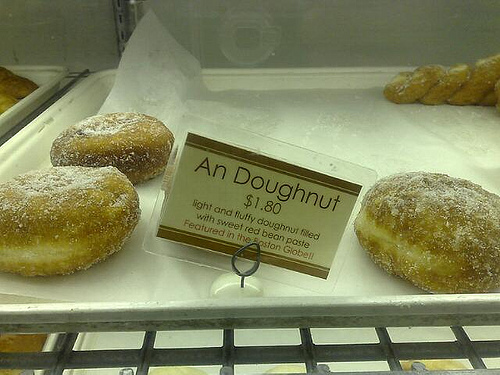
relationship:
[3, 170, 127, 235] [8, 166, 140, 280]
powder sugar on doughnut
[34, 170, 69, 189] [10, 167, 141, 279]
powder sugar on donut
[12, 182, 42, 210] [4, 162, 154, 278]
powder sugar on donut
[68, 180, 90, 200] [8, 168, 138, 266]
powder sugar on donut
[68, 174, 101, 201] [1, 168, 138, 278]
powder sugar on donut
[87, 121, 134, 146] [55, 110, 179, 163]
powder sugar on donut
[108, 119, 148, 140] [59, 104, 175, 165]
powder sugar on donut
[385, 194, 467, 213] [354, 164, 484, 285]
powder sugar on donut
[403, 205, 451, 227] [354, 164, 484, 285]
powder sugar on donut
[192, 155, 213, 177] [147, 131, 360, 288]
letter on sign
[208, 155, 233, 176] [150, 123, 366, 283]
letter on tag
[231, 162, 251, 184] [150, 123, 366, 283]
letter on tag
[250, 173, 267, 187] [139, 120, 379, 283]
letter on sign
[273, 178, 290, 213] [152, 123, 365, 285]
letter on sign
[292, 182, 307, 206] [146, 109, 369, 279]
letter on sign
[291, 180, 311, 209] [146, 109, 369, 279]
letter on sign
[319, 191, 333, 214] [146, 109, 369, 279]
letter on sign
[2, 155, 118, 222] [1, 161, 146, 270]
topping on donut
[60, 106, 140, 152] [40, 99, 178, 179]
topping on donut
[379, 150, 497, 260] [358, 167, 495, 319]
topping on donut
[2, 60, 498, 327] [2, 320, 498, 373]
tray on stand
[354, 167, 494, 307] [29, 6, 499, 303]
donut on paper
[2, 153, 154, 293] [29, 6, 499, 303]
donut on paper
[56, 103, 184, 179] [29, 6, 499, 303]
donut on paper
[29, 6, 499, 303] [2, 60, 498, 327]
paper on tray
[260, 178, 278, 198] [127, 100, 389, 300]
letter on sign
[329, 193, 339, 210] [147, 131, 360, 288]
letter on sign